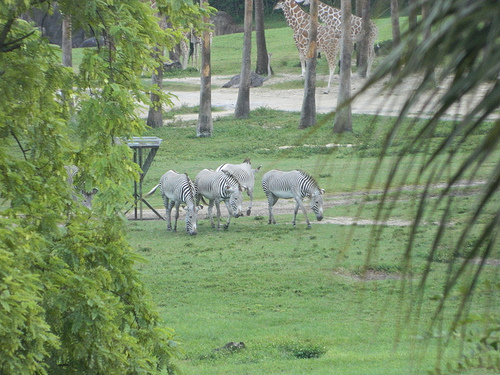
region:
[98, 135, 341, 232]
four zebras are together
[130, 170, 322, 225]
the zebras are grazing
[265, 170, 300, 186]
stripes on the zebra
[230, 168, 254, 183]
stripes on the zebra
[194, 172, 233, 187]
stripes on the zebra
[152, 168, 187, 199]
stripes on hte zebra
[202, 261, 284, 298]
the grass is short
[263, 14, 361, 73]
giraffes behind the trees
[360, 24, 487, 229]
long leaves of trees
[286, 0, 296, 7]
brown spot on giraffe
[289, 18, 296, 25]
brown spot on giraffe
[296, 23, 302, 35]
brown spot on giraffe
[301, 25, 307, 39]
brown spot on giraffe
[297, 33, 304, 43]
brown spot on giraffe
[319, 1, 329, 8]
brown spot on giraffe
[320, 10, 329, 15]
brown spot on giraffe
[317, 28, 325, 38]
brown spot on giraffe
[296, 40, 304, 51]
brown spot on giraffe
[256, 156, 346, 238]
This is a zebra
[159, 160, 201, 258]
This is a zebra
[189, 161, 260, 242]
This is a zebra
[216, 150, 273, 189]
This is a zebra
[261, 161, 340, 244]
This is a zebra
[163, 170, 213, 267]
This is a zebra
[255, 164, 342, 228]
This is a zebra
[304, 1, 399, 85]
This is a giraffe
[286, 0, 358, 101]
This is a giraffe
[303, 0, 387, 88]
This is a giraffe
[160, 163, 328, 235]
four zebras are grazing.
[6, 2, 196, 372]
tree in the foreground.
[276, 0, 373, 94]
two giraffes in the background.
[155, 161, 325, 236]
the zebras are getting something to eat.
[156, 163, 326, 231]
four zebras side by side.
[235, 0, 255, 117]
slender tree trunk in background.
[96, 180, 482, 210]
small path behind the zebras.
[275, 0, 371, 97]
the two giraffes are standing.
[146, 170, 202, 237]
the zebra is eating.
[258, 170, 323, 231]
the zebra is standing.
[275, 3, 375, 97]
two tall giraffes in back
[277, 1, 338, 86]
one tall giraffe in back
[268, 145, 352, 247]
one zebra eating grass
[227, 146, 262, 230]
one zebra eating grass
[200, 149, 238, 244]
one zebra eating grass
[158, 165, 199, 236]
one zebra eating grass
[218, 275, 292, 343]
area of green grass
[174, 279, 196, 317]
area of green grass